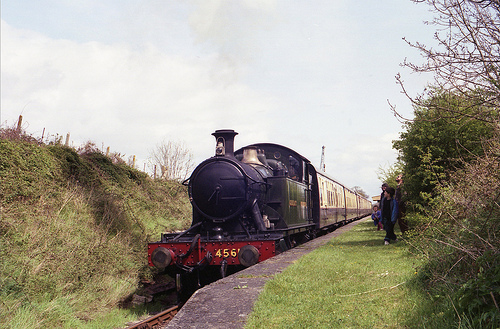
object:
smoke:
[184, 0, 280, 129]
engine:
[145, 129, 309, 274]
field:
[254, 206, 423, 324]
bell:
[214, 135, 228, 156]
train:
[146, 129, 372, 265]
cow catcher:
[146, 236, 285, 265]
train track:
[123, 303, 183, 328]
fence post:
[17, 115, 24, 132]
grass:
[1, 206, 449, 328]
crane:
[319, 145, 330, 177]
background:
[2, 2, 396, 173]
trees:
[395, 96, 500, 209]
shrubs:
[412, 197, 496, 310]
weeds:
[20, 179, 143, 268]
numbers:
[215, 248, 246, 258]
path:
[170, 214, 372, 325]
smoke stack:
[212, 129, 238, 156]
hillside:
[1, 135, 192, 318]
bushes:
[392, 94, 498, 324]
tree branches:
[147, 141, 197, 184]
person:
[383, 187, 399, 246]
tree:
[384, 1, 494, 182]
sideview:
[387, 1, 499, 328]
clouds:
[4, 23, 185, 140]